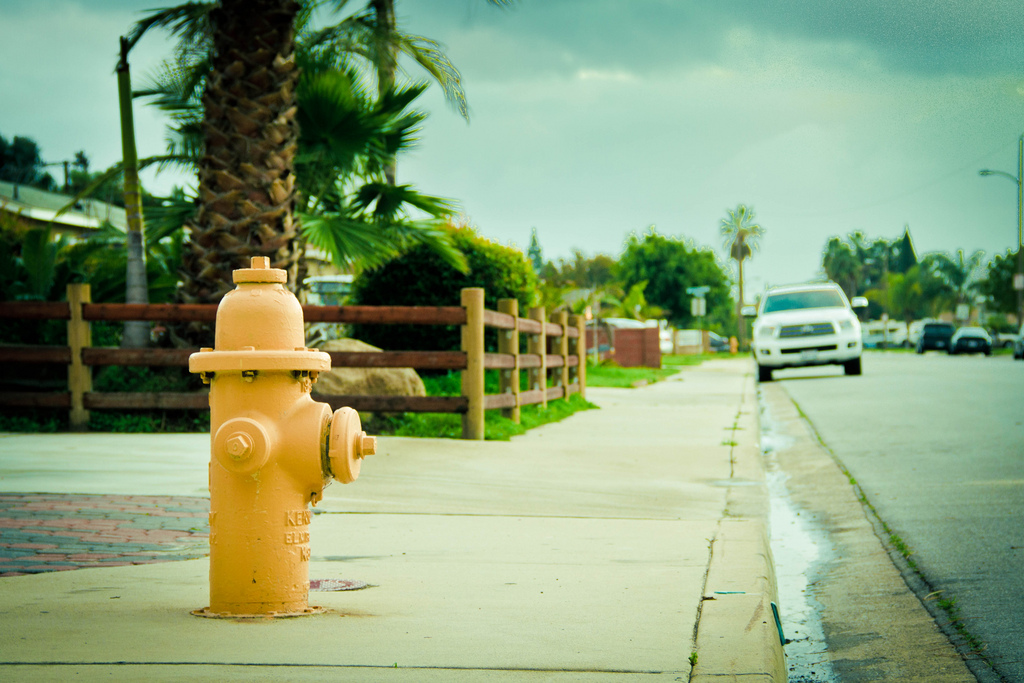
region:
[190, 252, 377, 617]
Yellow fire hydrant on a sidewalk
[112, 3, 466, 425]
Palm tree near a sidewalk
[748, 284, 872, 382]
White truck parked on a street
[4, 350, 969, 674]
Sidewalk next to a street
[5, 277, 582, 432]
Wood fence near a sidewalk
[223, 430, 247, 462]
Bolt on a fire hydrant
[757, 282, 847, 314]
Windshield on a truck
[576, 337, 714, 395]
Green grass near a sidewalk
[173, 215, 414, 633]
a yellow fire hydrant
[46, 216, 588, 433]
a brown wooden fence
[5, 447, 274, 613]
patch on the sidewalk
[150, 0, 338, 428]
trunk of a tree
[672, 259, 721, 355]
sign in the distance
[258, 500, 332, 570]
writing on the hydrant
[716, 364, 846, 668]
water on the ground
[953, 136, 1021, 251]
a curved light pole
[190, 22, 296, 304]
the trunk of a tree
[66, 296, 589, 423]
a wooden fence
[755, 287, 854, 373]
a white truck parked on the street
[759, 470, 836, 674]
water in a gutter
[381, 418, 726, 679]
the sidewalk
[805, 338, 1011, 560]
the street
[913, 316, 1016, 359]
cars parked on the street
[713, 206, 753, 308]
a tall palm tree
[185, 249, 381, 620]
Yellow fire hydrant in sidewalk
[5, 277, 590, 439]
Wooden post and rail fence around yard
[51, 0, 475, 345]
Very fat palm tree behind fence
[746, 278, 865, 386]
White SUV parked at curb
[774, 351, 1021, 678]
Asphalt street with concrete gutter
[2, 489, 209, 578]
Red and green tiled area in sidewalk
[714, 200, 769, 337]
Very tall palm tree in distance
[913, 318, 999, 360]
Vehicles parked on side of road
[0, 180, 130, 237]
Light colored house roof behind fence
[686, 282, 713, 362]
Sign post with green street sign at top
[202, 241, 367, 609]
yellow fire hydrant on sidewalk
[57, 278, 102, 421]
short round fence post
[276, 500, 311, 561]
letters on yellow fire hydrant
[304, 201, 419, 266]
large green leaves on tree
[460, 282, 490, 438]
short round fence post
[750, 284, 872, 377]
the front of a white vehicle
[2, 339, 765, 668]
a long sidewalk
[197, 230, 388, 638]
a small yellow fire hydrant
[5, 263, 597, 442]
a large wooden fence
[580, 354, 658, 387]
a section of green grass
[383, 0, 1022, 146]
dark storm clouds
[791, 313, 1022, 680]
a paved road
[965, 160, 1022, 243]
a tall street light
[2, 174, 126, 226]
the roof of a home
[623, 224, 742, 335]
a tall green tree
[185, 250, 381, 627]
fire hydrant painted yellow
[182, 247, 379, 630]
fire hydrant sticks out of sidewalk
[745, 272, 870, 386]
truck parked on street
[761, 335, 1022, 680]
street next to sidewalk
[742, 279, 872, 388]
truck next to sidewalk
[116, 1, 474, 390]
tree behind yellow fire hydrant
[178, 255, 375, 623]
The yellow hydrant on the sidewalk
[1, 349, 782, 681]
The sidewalk stretching to the horizon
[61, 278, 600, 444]
The wooden fence in the yard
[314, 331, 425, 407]
The boulder in the yard.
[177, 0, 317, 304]
The trunk of the palm tree in the yard